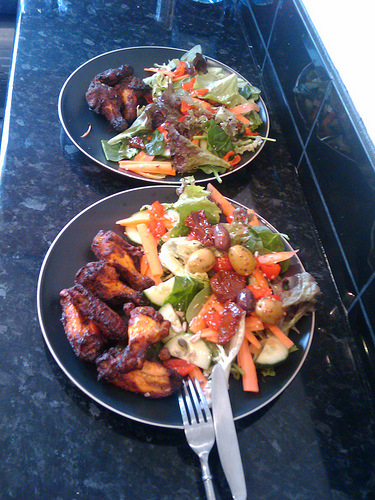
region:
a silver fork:
[170, 374, 220, 494]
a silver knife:
[206, 361, 258, 499]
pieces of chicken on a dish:
[55, 229, 175, 404]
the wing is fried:
[52, 278, 127, 364]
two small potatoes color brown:
[189, 239, 289, 327]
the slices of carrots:
[239, 314, 266, 394]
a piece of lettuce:
[172, 186, 221, 219]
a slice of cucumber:
[136, 271, 181, 308]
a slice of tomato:
[189, 293, 238, 342]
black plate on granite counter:
[49, 175, 352, 406]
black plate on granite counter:
[56, 31, 283, 179]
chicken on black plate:
[82, 306, 164, 371]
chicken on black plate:
[90, 65, 133, 118]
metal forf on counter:
[181, 381, 247, 481]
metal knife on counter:
[205, 363, 264, 498]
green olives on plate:
[229, 253, 249, 273]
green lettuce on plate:
[158, 116, 223, 165]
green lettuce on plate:
[179, 199, 222, 230]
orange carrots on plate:
[232, 350, 258, 404]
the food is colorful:
[85, 38, 266, 170]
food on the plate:
[21, 174, 317, 417]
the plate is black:
[22, 188, 322, 432]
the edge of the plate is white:
[28, 184, 317, 421]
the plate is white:
[34, 183, 320, 448]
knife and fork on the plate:
[159, 363, 252, 496]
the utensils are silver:
[171, 358, 253, 498]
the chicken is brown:
[53, 219, 183, 397]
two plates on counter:
[2, 24, 319, 497]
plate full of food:
[58, 45, 267, 185]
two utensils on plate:
[178, 362, 247, 498]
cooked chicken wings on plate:
[63, 233, 173, 399]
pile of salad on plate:
[122, 50, 255, 178]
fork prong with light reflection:
[178, 378, 213, 458]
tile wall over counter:
[251, 2, 373, 328]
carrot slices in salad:
[238, 320, 293, 390]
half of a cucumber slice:
[164, 333, 211, 369]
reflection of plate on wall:
[293, 61, 356, 162]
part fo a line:
[321, 219, 348, 252]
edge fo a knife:
[216, 456, 240, 481]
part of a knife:
[219, 403, 232, 433]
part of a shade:
[329, 407, 357, 437]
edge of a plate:
[164, 414, 186, 431]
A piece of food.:
[190, 248, 213, 268]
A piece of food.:
[234, 244, 258, 277]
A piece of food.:
[235, 288, 252, 304]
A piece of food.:
[208, 266, 239, 296]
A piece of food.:
[250, 295, 287, 315]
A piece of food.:
[202, 309, 216, 330]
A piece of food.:
[166, 335, 212, 358]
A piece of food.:
[118, 302, 178, 367]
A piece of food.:
[75, 263, 145, 308]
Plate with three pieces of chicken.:
[57, 44, 268, 185]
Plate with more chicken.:
[36, 184, 315, 429]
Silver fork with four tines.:
[175, 375, 216, 498]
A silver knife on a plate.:
[211, 363, 248, 499]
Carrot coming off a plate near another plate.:
[207, 181, 234, 221]